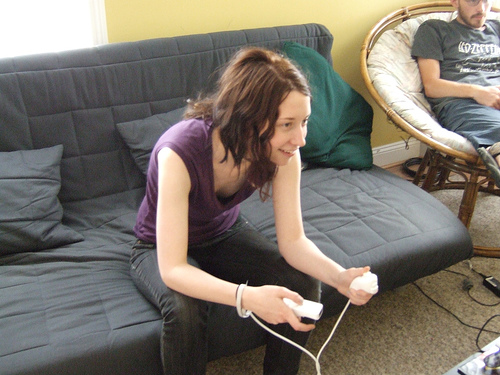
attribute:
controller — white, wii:
[348, 270, 381, 298]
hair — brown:
[184, 47, 315, 204]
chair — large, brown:
[359, 0, 499, 258]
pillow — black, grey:
[2, 143, 87, 257]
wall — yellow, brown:
[106, 1, 412, 149]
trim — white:
[372, 138, 426, 169]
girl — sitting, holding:
[131, 47, 380, 373]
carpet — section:
[206, 165, 499, 373]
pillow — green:
[277, 40, 374, 171]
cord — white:
[249, 295, 354, 373]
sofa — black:
[0, 23, 473, 374]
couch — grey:
[1, 23, 475, 373]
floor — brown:
[388, 303, 453, 357]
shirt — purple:
[133, 113, 273, 247]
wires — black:
[412, 259, 500, 351]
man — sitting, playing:
[415, 1, 499, 182]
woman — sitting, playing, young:
[129, 46, 376, 374]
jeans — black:
[131, 218, 321, 374]